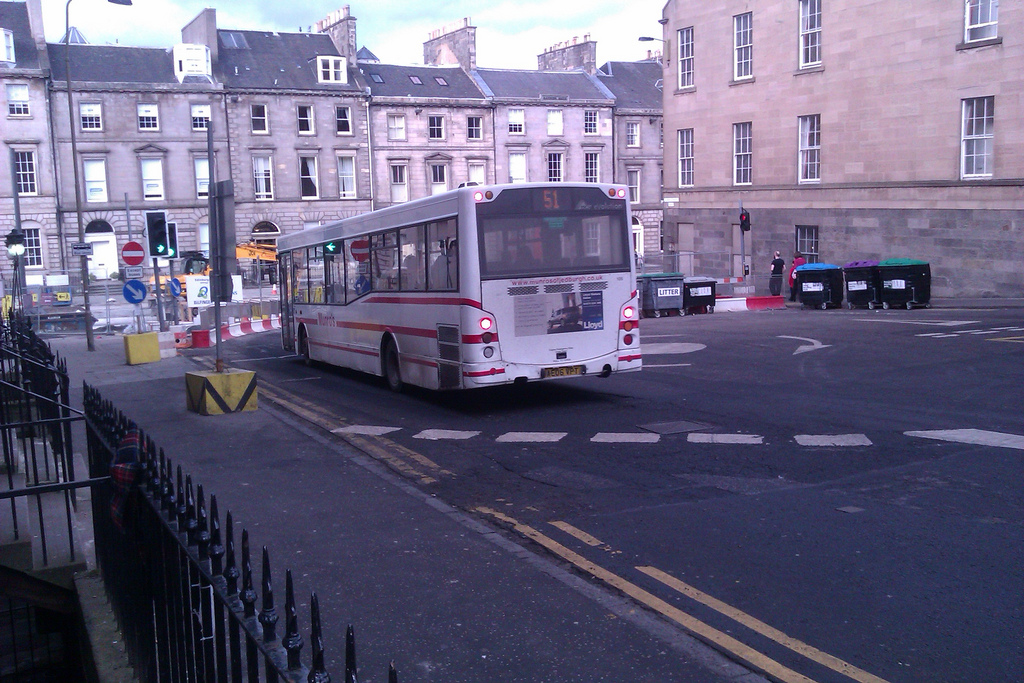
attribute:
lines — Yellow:
[344, 409, 839, 670]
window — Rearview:
[408, 207, 675, 347]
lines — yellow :
[397, 456, 702, 609]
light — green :
[113, 197, 227, 302]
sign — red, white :
[96, 221, 167, 291]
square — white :
[318, 404, 399, 442]